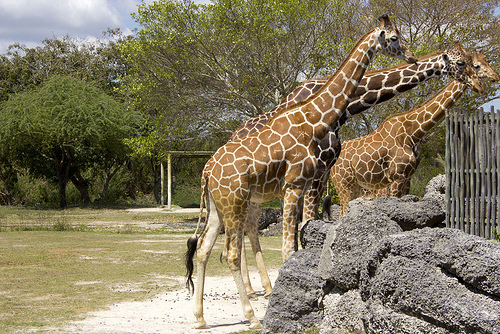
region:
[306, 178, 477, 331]
big, gray rock fence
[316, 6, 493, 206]
the giraffes are looking down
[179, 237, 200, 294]
Giraffe's long black tail.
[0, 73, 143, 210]
Green medium sized tree in zoo.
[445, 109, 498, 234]
Wooden fence enclosure in zoo.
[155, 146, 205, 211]
Wooden outdoor structure.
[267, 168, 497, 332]
Pile of gray porous rocks.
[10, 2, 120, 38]
Cloudy blue sky.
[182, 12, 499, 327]
Family of three giraffe's in zoo.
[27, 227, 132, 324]
Barren ground devoid of vegetation.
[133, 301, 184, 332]
White sandy dirt inside zoo enclosure.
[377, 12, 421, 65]
Head of adult giraffe.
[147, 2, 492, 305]
there are three giraffes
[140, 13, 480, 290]
giraffes have brown spots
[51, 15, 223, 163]
the trees have leaves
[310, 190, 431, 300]
the rocks are a barrier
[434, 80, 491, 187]
the fencing is wood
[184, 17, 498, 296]
the giraffes are in a zoo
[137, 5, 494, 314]
the giraffes are captive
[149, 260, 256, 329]
the ground by the fence is sandy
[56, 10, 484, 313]
three giraffes are a herd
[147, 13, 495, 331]
giraffes look over the fence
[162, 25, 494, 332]
three giraffes all together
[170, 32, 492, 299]
three giraffes standing together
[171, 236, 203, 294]
black bushy tail of giraffe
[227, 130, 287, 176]
orange and white spots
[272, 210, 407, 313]
rocks by leg of giraffe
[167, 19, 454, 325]
giraffes standing by rocks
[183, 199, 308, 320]
long white legs of giraffes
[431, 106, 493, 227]
wooden fence by giraffes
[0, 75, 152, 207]
large green trees by giraffes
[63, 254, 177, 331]
sand and grass on the ground